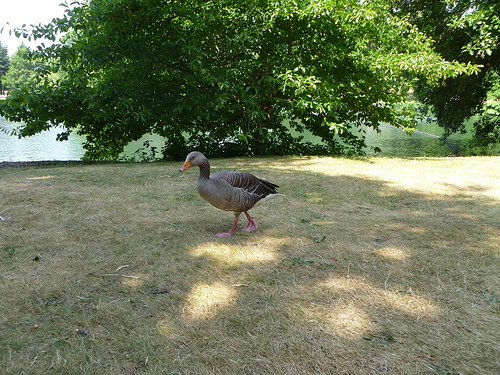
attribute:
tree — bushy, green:
[416, 0, 498, 140]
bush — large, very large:
[8, 4, 453, 161]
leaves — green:
[425, 49, 492, 78]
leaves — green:
[8, 21, 82, 48]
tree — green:
[2, 1, 469, 185]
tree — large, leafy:
[17, 21, 437, 131]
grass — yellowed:
[17, 191, 485, 349]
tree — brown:
[13, 10, 455, 174]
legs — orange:
[207, 214, 267, 246]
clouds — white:
[0, 4, 57, 21]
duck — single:
[178, 144, 290, 250]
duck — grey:
[173, 141, 285, 238]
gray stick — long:
[398, 125, 443, 140]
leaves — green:
[301, 227, 329, 248]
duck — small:
[185, 143, 287, 243]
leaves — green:
[220, 11, 287, 66]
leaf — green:
[91, 101, 101, 111]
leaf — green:
[87, 85, 99, 94]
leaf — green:
[171, 88, 198, 110]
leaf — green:
[129, 74, 134, 80]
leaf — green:
[102, 24, 118, 44]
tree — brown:
[0, 2, 287, 153]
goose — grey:
[180, 147, 276, 240]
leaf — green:
[227, 33, 232, 36]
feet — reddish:
[208, 205, 285, 245]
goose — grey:
[180, 146, 283, 237]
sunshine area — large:
[281, 5, 483, 127]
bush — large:
[0, 1, 499, 149]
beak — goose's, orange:
[158, 138, 209, 191]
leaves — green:
[155, 56, 292, 128]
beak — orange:
[178, 160, 189, 170]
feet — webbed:
[215, 219, 259, 236]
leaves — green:
[62, 0, 452, 152]